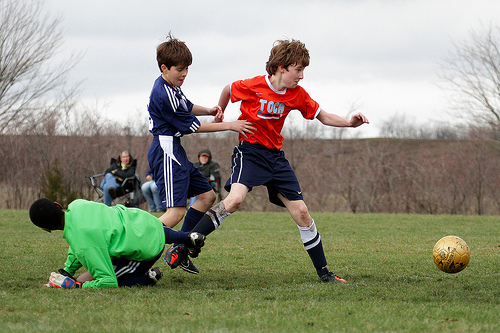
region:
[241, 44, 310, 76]
boy has red hair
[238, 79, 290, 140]
red and grey shirt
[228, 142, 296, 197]
blue and white shorts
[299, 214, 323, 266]
black and white socks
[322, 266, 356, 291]
black and red shoes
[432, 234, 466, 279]
gold ball on ground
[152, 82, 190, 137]
blue and white shirt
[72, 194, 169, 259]
boy has green shirt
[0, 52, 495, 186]
bare trees behind field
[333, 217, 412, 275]
green and short grass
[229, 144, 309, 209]
a boy's blue shorts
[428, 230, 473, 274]
a gold soccer ball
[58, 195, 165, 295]
a green long sleeve shirt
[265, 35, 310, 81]
a boy's short cut brown hair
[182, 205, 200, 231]
part of a long blue sock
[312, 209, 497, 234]
a section of green grass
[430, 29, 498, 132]
part of a tree with no leaves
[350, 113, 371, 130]
the hand of a boy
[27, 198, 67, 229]
a boy's short cut black hair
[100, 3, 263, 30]
part of a white sky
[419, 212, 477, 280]
The ball is yellow.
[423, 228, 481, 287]
The ball is round.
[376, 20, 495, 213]
The trees are bare of leaves.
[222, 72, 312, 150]
The boy is wearing a red shirt.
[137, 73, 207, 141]
The boy is wearing a blue shirt.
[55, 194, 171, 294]
The boy is wearing a green shirt.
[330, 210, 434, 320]
The grass is green.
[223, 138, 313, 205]
The boy is wearing blue shorts.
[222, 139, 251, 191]
The shorts have a white stripe on the leg.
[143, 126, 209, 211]
The boy is wearing blue shorts.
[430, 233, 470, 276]
a yellow soccer ball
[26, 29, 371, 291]
three kids playing soccer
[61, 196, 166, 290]
long sleeved green shirt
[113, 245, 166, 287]
black shorts with white stripes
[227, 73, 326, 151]
a red tshirt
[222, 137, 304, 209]
blue shorts with two white stripes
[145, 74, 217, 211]
matching blue shirt and shorts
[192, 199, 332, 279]
pair of black socks over shin guards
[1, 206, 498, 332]
a grassy field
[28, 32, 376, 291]
three boys playing soccer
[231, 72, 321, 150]
red top of boy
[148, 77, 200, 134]
blue and white top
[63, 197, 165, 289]
green top boy is wearing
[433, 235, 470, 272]
soccer ball in the air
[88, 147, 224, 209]
two women sitting in chairs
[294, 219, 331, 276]
black and white socks boy is wearing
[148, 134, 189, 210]
blue and white shorts boy is wearing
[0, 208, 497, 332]
green grass boys are playing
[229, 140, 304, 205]
black and white shorts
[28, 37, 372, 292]
Three boys playing soccer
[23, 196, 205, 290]
Boy in a green shirt on the ground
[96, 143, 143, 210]
Man sitting in a chair on the sideline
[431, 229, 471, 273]
Gold soccer ball in the grass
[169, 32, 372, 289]
Boy trying to get to the soccer ball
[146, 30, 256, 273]
Boy trying to stop the boy in front of him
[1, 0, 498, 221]
Leafless trees behind the field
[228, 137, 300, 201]
Blue shorts on the player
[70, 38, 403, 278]
these are children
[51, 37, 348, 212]
the kids are playing soccer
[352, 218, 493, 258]
this is a soccer ball